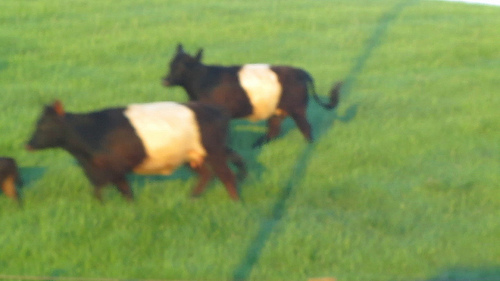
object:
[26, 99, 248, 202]
cow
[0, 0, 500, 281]
grass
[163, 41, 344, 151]
cow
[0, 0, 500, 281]
field